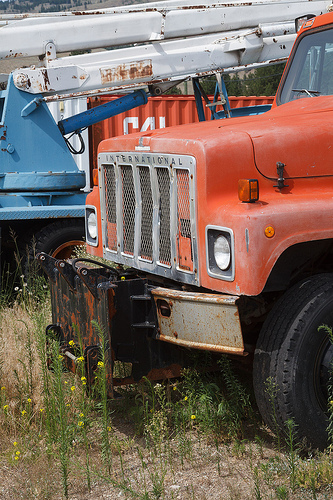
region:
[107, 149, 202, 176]
LETTERING ON FRONT OF TRUCK IS INTERNATIONAL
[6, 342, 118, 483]
YELLOW FLOWERS ARE GROWING IN FRONT OF TRUCK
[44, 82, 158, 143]
A BLUE SHOCK IS ON A MACHINE BEHIND THE TRUCK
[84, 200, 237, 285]
TRUCK HAS TWO HEAD LIGHTS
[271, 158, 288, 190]
A LOCK IS LOCATED ON THE HOOD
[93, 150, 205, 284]
GRILL ON TRUCK HAS FIVE SECTIONS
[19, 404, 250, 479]
MAIN COLOR OF GROUND IS BROWN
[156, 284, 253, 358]
BUMPER OF TRUCK HAS RUST ON IT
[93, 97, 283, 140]
TRAILER BEHIND TRUCK IS ORANGE IN COLOR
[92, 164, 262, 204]
TWO ORANGE LIGHTS ARE OVER THE WHEELS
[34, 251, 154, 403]
heavy machinery on front of truck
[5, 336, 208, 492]
large weeds growing yellow flowers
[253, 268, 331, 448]
over sized large tire on truck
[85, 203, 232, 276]
small headlights on large truck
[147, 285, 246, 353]
rust covered truck shows it has some age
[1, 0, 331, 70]
white hydrolic machinery on truck shows unprotected by weather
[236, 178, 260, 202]
orange reflector lights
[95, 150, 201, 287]
piece of metal on truck displays "international" brand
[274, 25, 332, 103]
windshield on truck looks clean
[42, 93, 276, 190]
large cargo units in background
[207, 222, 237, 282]
head light on an orange truck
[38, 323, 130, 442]
yellow flowers on tall weeds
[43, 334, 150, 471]
tall wispy weeds growing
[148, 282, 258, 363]
rusty truck bumper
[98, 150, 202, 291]
metal grate on the front of a truck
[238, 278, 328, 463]
front tire of a truck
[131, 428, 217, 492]
tan ground with weeds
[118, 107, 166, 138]
white numbers on an orange container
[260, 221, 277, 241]
orange circular light on the side of an orange truck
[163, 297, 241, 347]
rust spots on a bumper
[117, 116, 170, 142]
white lettering on orange background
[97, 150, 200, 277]
silver front grill of truck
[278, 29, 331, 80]
front windshield of orange truck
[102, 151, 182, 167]
letters embossed in front grill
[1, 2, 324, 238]
blue and white lift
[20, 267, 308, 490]
green weeds with yellow flowers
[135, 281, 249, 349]
front bumper of orange truck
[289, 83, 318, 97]
windshield wiper on front windshield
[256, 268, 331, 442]
black front wheel of orange truck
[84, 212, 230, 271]
front headlights of orange truck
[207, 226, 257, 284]
left light of jeep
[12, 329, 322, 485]
a beuatiful view of trees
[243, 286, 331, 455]
wheel of the jeep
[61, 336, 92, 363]
a small yellow flowers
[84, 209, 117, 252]
right light of the jeep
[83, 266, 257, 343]
a broken part of jeep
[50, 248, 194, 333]
front part of the jeep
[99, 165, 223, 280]
front window of the jeep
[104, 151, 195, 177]
name of the jeep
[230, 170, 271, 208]
a small object on jeep